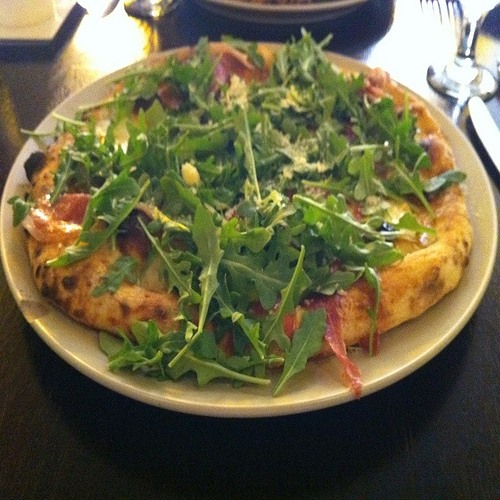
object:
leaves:
[101, 73, 396, 259]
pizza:
[19, 35, 474, 367]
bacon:
[322, 283, 362, 400]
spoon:
[443, 55, 477, 122]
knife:
[467, 95, 499, 176]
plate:
[0, 42, 499, 420]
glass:
[130, 1, 187, 16]